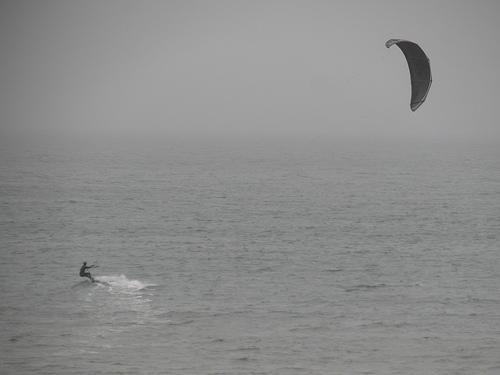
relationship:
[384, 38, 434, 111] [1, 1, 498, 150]
parasail in sky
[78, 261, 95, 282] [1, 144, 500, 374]
person in ocean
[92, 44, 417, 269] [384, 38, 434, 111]
rope connected to parasail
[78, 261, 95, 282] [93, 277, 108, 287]
person on a surfboard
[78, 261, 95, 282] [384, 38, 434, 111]
person using parasail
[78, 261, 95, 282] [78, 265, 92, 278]
person wearing a wet suit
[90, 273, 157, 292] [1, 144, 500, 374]
foam in ocean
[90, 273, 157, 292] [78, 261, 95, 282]
foam left by person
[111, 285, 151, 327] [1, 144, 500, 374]
path in ocean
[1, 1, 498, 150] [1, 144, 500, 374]
sky above ocean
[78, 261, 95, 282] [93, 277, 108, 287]
person standing on surfboard